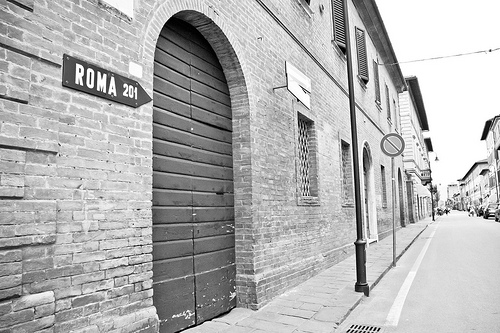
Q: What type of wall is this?
A: Brick.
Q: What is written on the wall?
A: ROMA 201.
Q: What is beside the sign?
A: Door.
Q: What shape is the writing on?
A: An arrow.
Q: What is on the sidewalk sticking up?
A: A pole.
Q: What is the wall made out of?
A: Brick.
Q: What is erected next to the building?
A: Metal pole.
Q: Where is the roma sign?
A: On the brick wall.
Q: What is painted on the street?
A: White line.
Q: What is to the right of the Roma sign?
A: Door.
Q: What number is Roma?
A: 201.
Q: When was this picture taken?
A: Daytime.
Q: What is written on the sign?
A: ROMA 201.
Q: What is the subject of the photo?
A: Street.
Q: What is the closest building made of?
A: Brick.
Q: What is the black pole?
A: Streetlight.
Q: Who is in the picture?
A: No one.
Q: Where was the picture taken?
A: Italy.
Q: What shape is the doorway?
A: Arch.